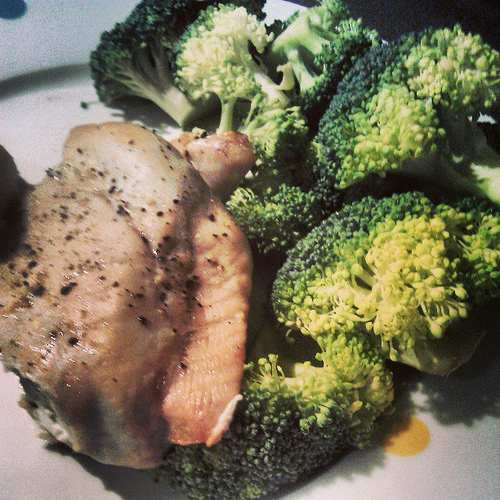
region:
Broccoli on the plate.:
[289, 225, 476, 372]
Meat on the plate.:
[31, 158, 238, 475]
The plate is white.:
[0, 19, 113, 131]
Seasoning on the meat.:
[41, 212, 205, 364]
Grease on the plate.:
[368, 387, 439, 461]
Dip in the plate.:
[11, 45, 87, 108]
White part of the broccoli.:
[200, 9, 272, 98]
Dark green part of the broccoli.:
[338, 34, 394, 88]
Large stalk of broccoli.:
[343, 26, 496, 192]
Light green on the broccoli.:
[369, 242, 448, 317]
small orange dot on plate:
[381, 413, 428, 454]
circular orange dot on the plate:
[380, 415, 427, 454]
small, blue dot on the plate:
[1, 0, 26, 20]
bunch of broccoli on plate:
[89, 0, 496, 496]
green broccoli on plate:
[88, 0, 498, 499]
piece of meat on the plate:
[0, 122, 255, 467]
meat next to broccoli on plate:
[0, 120, 251, 467]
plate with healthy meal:
[0, 0, 496, 496]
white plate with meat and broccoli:
[0, 1, 496, 496]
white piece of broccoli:
[176, 6, 268, 133]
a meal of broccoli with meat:
[8, 7, 498, 498]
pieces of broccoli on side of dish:
[220, 0, 499, 491]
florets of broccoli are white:
[191, 9, 278, 100]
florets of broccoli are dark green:
[309, 60, 374, 116]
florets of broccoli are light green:
[349, 224, 469, 359]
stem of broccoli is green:
[136, 72, 202, 134]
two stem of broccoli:
[273, 10, 334, 87]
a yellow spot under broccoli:
[373, 397, 439, 467]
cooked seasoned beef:
[0, 102, 292, 489]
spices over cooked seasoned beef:
[7, 132, 229, 397]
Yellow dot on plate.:
[361, 390, 436, 471]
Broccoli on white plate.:
[230, 310, 410, 482]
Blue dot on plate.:
[1, 0, 36, 25]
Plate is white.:
[34, 5, 154, 162]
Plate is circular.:
[45, 2, 408, 89]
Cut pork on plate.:
[23, 73, 278, 400]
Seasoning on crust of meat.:
[35, 193, 150, 346]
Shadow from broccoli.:
[399, 282, 499, 447]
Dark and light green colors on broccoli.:
[301, 25, 453, 168]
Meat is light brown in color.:
[28, 120, 294, 456]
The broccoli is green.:
[269, 196, 499, 370]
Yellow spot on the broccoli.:
[318, 243, 454, 355]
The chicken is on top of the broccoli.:
[8, 121, 258, 468]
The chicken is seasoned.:
[1, 118, 254, 478]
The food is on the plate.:
[7, 3, 459, 496]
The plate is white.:
[60, 95, 495, 496]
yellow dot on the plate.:
[374, 413, 427, 461]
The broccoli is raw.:
[265, 185, 495, 386]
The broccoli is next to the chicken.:
[99, 0, 499, 497]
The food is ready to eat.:
[14, 93, 497, 496]